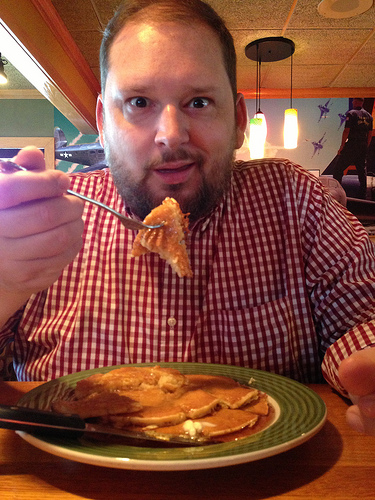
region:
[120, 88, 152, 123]
THAT IS AN EYE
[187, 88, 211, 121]
THAT IS AN EYE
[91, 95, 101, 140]
THAT IS AN EAR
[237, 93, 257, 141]
THAT IS AN EYE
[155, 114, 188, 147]
THAT IS THE NOSE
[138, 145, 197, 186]
THAT IS THE MOUTH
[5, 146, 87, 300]
THAT IS THE HAND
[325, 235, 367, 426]
THAT IS THE HAND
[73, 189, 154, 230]
THAT IS A FORK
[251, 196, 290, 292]
THIS IS A CHECKED SHIRT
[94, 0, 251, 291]
this guy is about to enjoy a bite of pancake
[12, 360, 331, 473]
a plate of pancakes drowned in syrup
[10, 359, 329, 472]
the serving plate is green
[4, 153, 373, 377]
this guy is wearing a red checked shirt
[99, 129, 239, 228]
this guy has a mustache and beard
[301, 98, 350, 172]
a mural featuring fighter planes is on the far wall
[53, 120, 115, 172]
another fighter plane on the back wall mural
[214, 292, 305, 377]
the man's shirt has a breast pocket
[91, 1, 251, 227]
our pancake lover has a receding hairline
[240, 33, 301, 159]
lights hang from the ceiling behind our pancake fan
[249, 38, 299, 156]
glowing light hanging from ceiling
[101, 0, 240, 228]
balding man with facial hair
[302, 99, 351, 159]
plane picture on wall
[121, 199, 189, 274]
pancake on end of fork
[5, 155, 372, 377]
red and white checkered shirt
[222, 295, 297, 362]
pocket on front of shirt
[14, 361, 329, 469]
green plate with white trim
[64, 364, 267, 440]
pile of cut pancakes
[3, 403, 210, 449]
black handle on knife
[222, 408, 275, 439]
maple syrup on plate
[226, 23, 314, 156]
lights hanging from the ceiling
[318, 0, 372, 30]
a white speaker on the ceiling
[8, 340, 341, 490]
a green plate with pancakes on it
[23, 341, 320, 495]
a green plate with food on it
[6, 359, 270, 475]
a knife on a green plate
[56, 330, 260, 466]
pancakes with maple syrup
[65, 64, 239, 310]
a man eating pancakes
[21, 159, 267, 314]
a silver fork with a piece of a pancake on it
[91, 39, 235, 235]
a man with facial hair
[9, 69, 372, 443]
a man wearing a plaid shirt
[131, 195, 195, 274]
piece of pancake on a fork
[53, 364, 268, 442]
pancakes on a plate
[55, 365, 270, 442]
pancakes covered in syrup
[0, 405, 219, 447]
knife on the plate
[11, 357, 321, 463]
plate of pancakes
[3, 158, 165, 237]
fork spearing a peace of pancake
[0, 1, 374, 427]
man eating pancakes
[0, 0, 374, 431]
man wearing a red and white plaid shirt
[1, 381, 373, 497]
brown wooden table